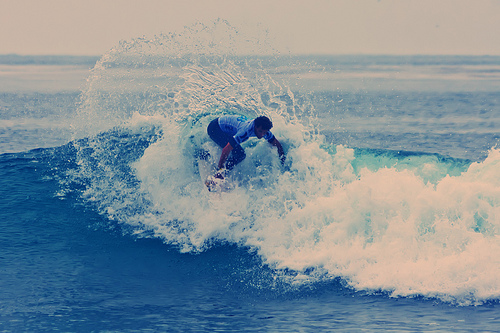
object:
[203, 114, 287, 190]
man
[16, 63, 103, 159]
water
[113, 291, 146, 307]
water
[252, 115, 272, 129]
hair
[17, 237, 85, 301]
water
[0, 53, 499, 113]
ocean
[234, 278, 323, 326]
water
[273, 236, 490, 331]
ocean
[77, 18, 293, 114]
splashing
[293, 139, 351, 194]
wave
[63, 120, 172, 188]
wave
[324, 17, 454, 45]
sky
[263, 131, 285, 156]
arm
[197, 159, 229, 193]
surfboard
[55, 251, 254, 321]
ocean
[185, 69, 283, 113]
wave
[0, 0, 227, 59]
sky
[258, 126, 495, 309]
waves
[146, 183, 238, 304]
water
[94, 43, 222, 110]
wave